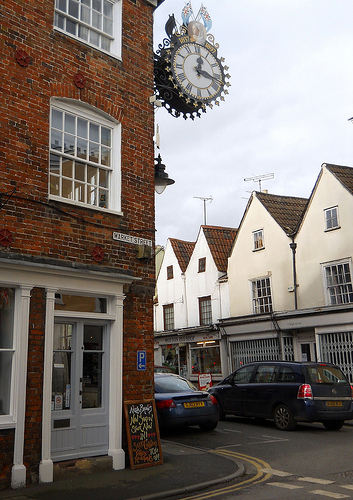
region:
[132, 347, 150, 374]
Parking permitted street sign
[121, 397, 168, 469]
Propped up cafe menu chalkboard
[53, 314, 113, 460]
Grey door with windows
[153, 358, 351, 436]
Two cars parked on street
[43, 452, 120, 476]
Brown cement door step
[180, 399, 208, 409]
Black and yellow license plate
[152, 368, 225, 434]
Rear of blue car parked in street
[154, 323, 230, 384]
Shop on side of street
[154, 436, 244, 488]
Curb and sidewalk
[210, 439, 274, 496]
Yellow double stripes lining curve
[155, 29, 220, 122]
white clock on wall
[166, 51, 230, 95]
white face on clock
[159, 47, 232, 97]
clock has roman numerals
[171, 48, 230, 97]
roman numerals are black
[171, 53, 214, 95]
clock has black hands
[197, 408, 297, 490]
yellow lines on road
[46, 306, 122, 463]
white doors on building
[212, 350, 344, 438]
blue van on road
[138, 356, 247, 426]
blue car on road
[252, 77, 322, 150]
grey and white sky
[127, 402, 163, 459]
drawing in on the board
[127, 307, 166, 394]
the bricks are brown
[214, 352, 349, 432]
the car is blue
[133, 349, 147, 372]
parking is to the left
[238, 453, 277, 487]
the two lines are yellow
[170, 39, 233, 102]
the time is 12.15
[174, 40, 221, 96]
the numbers are roamn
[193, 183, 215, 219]
tv earial is on the roof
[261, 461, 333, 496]
the lines are white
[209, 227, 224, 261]
the roof is brown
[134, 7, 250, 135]
white clock on building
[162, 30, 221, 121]
clock has roman numerals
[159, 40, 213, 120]
roman numerals are black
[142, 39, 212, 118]
clock has white face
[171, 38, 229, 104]
clock has black hands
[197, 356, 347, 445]
blue van is parked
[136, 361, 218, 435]
blue car is parked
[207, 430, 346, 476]
road is light grey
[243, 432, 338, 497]
yellow lines on road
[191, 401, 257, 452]
white lines on road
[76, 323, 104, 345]
window of a building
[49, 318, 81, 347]
window of a building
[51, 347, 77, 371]
window of a building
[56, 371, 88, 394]
window of a building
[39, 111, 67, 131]
window of a building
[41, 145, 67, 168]
window of a building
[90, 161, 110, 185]
window of a building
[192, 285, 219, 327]
window of a building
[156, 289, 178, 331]
window of a building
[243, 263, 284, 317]
window of a building